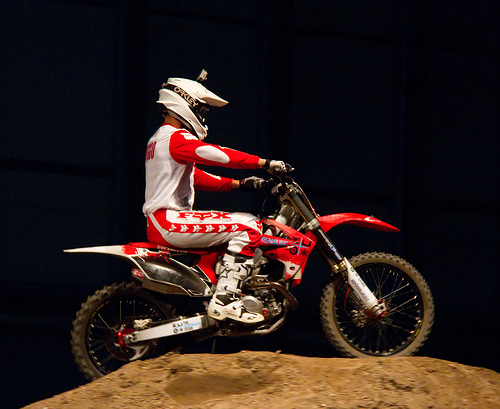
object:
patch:
[195, 145, 229, 163]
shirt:
[142, 123, 261, 217]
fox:
[177, 211, 232, 222]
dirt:
[21, 350, 499, 409]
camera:
[197, 69, 208, 82]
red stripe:
[152, 209, 262, 257]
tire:
[69, 281, 178, 381]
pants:
[146, 208, 263, 257]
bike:
[62, 163, 436, 382]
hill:
[13, 349, 500, 406]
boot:
[207, 249, 265, 326]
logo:
[173, 86, 198, 106]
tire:
[319, 251, 434, 358]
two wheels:
[70, 250, 434, 382]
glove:
[239, 176, 265, 189]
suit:
[143, 123, 262, 257]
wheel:
[69, 282, 179, 380]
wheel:
[320, 250, 436, 358]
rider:
[143, 77, 288, 326]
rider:
[135, 52, 265, 343]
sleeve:
[169, 129, 261, 169]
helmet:
[155, 77, 229, 140]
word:
[177, 211, 232, 222]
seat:
[129, 241, 211, 254]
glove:
[261, 159, 287, 177]